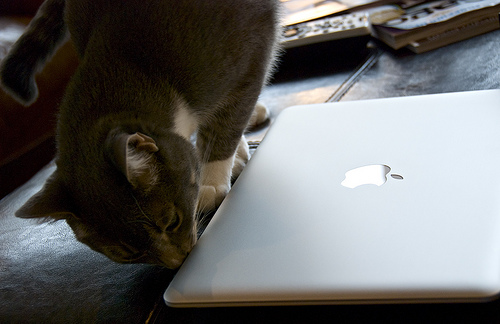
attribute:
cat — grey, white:
[2, 4, 280, 268]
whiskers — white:
[188, 125, 225, 235]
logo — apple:
[338, 163, 404, 193]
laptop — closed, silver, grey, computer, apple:
[163, 88, 499, 303]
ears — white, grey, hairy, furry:
[14, 129, 160, 225]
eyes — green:
[110, 207, 184, 264]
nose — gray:
[160, 254, 185, 269]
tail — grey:
[3, 0, 71, 106]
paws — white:
[192, 117, 252, 212]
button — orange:
[284, 28, 299, 38]